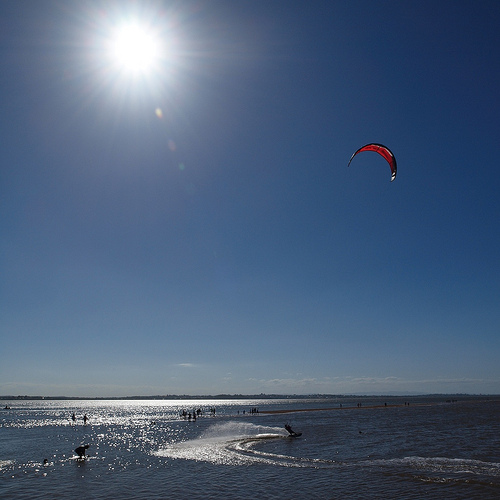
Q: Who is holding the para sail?
A: The man on the surfboard.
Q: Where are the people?
A: At the beach.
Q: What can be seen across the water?
A: Trees.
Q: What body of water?
A: Ocean.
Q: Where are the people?
A: Ocean.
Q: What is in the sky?
A: Sun.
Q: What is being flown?
A: Kite.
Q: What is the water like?
A: Calm.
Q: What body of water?
A: Ocean.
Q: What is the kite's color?
A: Red.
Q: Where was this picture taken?
A: At a beach.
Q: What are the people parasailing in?
A: Water.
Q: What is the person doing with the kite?
A: Parasailing.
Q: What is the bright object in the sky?
A: The sun.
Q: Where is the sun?
A: In the sky.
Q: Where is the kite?
A: In the sky.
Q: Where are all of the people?
A: In the water.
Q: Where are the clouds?
A: In the sky.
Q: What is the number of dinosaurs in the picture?
A: Zero.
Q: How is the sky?
A: Blue and sunny.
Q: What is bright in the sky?
A: The sun.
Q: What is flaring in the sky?
A: The sun.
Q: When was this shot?
A: Daytime.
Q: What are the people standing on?
A: Sandbar.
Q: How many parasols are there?
A: 1.